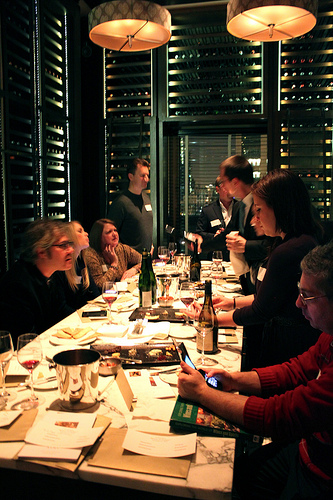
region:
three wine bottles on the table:
[17, 131, 321, 352]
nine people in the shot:
[36, 157, 313, 368]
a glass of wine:
[210, 249, 229, 278]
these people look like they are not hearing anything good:
[31, 201, 137, 287]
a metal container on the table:
[46, 349, 120, 417]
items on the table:
[111, 371, 188, 461]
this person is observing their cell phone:
[164, 262, 318, 422]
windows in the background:
[93, 68, 295, 152]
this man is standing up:
[112, 154, 163, 246]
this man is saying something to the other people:
[208, 154, 257, 206]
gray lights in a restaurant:
[79, 2, 181, 62]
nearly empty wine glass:
[12, 330, 48, 399]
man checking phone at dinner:
[164, 247, 331, 452]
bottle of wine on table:
[130, 244, 163, 312]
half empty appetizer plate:
[84, 333, 190, 381]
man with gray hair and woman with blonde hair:
[2, 216, 95, 336]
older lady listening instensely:
[88, 214, 140, 292]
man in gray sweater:
[114, 154, 171, 276]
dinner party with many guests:
[1, 152, 331, 495]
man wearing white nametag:
[115, 151, 166, 264]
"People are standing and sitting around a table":
[0, 144, 332, 498]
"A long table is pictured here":
[0, 192, 260, 495]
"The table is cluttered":
[0, 223, 255, 498]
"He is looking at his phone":
[169, 235, 330, 497]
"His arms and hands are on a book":
[164, 234, 330, 448]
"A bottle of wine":
[186, 275, 223, 368]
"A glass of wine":
[13, 333, 50, 415]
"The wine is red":
[98, 271, 123, 333]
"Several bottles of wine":
[104, 226, 240, 361]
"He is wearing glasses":
[280, 232, 331, 370]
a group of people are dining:
[19, 129, 323, 462]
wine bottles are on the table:
[132, 228, 228, 358]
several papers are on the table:
[6, 248, 229, 470]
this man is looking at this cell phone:
[172, 340, 223, 388]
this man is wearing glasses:
[50, 238, 78, 253]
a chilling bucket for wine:
[53, 343, 106, 409]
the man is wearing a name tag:
[137, 202, 158, 214]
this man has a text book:
[166, 391, 267, 452]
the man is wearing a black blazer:
[196, 199, 245, 251]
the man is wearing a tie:
[234, 202, 246, 233]